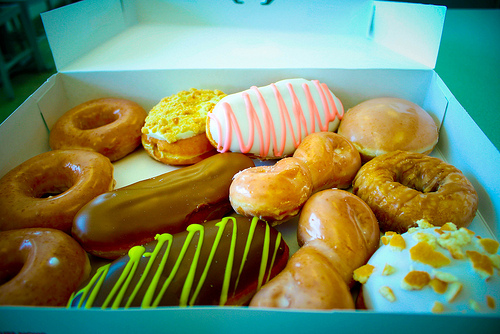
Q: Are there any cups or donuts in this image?
A: Yes, there is a donut.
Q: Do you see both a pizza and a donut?
A: No, there is a donut but no pizzas.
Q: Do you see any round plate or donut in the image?
A: Yes, there is a round donut.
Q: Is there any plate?
A: No, there are no plates.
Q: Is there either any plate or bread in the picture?
A: No, there are no plates or breads.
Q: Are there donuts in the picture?
A: Yes, there is a donut.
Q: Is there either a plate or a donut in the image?
A: Yes, there is a donut.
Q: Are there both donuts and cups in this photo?
A: No, there is a donut but no cups.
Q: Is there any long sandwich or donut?
A: Yes, there is a long donut.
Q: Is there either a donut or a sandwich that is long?
A: Yes, the donut is long.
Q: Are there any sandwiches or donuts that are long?
A: Yes, the donut is long.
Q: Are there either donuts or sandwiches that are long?
A: Yes, the donut is long.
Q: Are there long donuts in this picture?
A: Yes, there is a long donut.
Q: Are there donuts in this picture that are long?
A: Yes, there is a donut that is long.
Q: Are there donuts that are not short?
A: Yes, there is a long donut.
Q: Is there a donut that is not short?
A: Yes, there is a long donut.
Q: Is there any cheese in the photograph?
A: No, there is no cheese.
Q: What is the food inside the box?
A: The food is a donut.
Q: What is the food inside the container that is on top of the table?
A: The food is a donut.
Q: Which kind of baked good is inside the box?
A: The food is a donut.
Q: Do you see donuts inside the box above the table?
A: Yes, there is a donut inside the box.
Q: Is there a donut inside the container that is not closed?
A: Yes, there is a donut inside the box.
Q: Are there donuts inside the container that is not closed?
A: Yes, there is a donut inside the box.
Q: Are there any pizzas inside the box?
A: No, there is a donut inside the box.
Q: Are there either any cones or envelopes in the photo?
A: No, there are no envelopes or cones.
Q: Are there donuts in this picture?
A: Yes, there is a donut.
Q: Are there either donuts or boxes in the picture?
A: Yes, there is a donut.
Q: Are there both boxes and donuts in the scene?
A: Yes, there are both a donut and a box.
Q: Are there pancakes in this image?
A: No, there are no pancakes.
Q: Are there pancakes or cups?
A: No, there are no pancakes or cups.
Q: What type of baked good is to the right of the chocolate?
A: The food is a donut.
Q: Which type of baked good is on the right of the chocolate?
A: The food is a donut.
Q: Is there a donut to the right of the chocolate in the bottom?
A: Yes, there is a donut to the right of the chocolate.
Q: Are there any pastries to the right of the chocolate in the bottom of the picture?
A: No, there is a donut to the right of the chocolate.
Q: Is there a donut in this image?
A: Yes, there is a donut.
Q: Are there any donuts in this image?
A: Yes, there is a donut.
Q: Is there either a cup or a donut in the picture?
A: Yes, there is a donut.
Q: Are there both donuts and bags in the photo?
A: No, there is a donut but no bags.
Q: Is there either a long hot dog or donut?
A: Yes, there is a long donut.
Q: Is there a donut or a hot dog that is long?
A: Yes, the donut is long.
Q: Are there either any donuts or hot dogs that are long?
A: Yes, the donut is long.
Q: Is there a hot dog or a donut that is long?
A: Yes, the donut is long.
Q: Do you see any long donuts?
A: Yes, there is a long donut.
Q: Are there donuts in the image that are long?
A: Yes, there is a donut that is long.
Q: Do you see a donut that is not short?
A: Yes, there is a long donut.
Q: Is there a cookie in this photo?
A: No, there are no cookies.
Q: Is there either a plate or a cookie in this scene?
A: No, there are no cookies or plates.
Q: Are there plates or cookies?
A: No, there are no cookies or plates.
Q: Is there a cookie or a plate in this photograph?
A: No, there are no cookies or plates.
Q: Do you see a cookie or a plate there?
A: No, there are no cookies or plates.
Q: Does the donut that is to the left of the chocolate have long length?
A: Yes, the donut is long.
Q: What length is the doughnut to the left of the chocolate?
A: The doughnut is long.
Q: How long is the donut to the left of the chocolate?
A: The donut is long.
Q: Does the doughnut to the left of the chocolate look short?
A: No, the doughnut is long.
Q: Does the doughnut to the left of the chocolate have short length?
A: No, the doughnut is long.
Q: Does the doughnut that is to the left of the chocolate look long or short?
A: The doughnut is long.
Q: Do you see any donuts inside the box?
A: Yes, there is a donut inside the box.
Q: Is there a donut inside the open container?
A: Yes, there is a donut inside the box.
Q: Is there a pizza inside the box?
A: No, there is a donut inside the box.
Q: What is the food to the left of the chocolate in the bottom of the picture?
A: The food is a donut.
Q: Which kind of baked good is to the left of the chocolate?
A: The food is a donut.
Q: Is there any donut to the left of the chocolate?
A: Yes, there is a donut to the left of the chocolate.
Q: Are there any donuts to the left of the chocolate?
A: Yes, there is a donut to the left of the chocolate.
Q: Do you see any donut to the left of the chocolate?
A: Yes, there is a donut to the left of the chocolate.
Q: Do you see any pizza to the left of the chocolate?
A: No, there is a donut to the left of the chocolate.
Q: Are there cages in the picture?
A: No, there are no cages.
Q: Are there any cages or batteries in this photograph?
A: No, there are no cages or batteries.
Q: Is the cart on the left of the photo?
A: Yes, the cart is on the left of the image.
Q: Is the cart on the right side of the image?
A: No, the cart is on the left of the image.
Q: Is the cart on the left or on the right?
A: The cart is on the left of the image.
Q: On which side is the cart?
A: The cart is on the left of the image.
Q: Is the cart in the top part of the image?
A: Yes, the cart is in the top of the image.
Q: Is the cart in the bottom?
A: No, the cart is in the top of the image.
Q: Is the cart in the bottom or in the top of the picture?
A: The cart is in the top of the image.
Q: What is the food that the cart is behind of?
A: The food is donuts.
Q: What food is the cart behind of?
A: The cart is behind the doughnuts.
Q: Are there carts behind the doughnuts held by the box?
A: Yes, there is a cart behind the doughnuts.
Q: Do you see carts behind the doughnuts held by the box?
A: Yes, there is a cart behind the doughnuts.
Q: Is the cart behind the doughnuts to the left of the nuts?
A: Yes, the cart is behind the donuts.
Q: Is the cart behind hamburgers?
A: No, the cart is behind the donuts.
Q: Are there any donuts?
A: Yes, there is a donut.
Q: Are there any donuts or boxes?
A: Yes, there is a donut.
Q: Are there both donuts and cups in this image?
A: No, there is a donut but no cups.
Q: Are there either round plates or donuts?
A: Yes, there is a round donut.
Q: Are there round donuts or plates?
A: Yes, there is a round donut.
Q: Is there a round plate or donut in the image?
A: Yes, there is a round donut.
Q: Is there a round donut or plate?
A: Yes, there is a round donut.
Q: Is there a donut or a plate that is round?
A: Yes, the donut is round.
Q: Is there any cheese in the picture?
A: No, there is no cheese.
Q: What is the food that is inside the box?
A: The food is a donut.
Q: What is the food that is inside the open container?
A: The food is a donut.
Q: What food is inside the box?
A: The food is a donut.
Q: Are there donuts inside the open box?
A: Yes, there is a donut inside the box.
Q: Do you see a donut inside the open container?
A: Yes, there is a donut inside the box.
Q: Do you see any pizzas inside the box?
A: No, there is a donut inside the box.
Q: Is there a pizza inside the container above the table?
A: No, there is a donut inside the box.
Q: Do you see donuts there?
A: Yes, there is a donut.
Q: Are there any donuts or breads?
A: Yes, there is a donut.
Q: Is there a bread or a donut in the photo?
A: Yes, there is a donut.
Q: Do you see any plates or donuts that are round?
A: Yes, the donut is round.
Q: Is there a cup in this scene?
A: No, there are no cups.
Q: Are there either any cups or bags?
A: No, there are no cups or bags.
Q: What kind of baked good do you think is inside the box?
A: The food is a donut.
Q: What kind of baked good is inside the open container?
A: The food is a donut.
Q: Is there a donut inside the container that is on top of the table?
A: Yes, there is a donut inside the box.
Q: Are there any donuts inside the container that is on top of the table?
A: Yes, there is a donut inside the box.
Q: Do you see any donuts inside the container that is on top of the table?
A: Yes, there is a donut inside the box.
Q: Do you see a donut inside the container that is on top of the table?
A: Yes, there is a donut inside the box.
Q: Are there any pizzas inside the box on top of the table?
A: No, there is a donut inside the box.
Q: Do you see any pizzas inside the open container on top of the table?
A: No, there is a donut inside the box.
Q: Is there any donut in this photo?
A: Yes, there is a donut.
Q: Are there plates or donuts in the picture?
A: Yes, there is a donut.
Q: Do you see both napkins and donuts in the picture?
A: No, there is a donut but no napkins.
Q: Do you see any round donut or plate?
A: Yes, there is a round donut.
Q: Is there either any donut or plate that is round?
A: Yes, the donut is round.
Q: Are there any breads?
A: No, there are no breads.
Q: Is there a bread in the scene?
A: No, there is no breads.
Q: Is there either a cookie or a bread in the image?
A: No, there are no breads or cookies.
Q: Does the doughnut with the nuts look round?
A: Yes, the doughnut is round.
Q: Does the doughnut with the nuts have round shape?
A: Yes, the doughnut is round.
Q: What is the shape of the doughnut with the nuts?
A: The doughnut is round.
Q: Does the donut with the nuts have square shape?
A: No, the doughnut is round.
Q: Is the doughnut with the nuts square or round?
A: The donut is round.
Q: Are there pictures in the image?
A: No, there are no pictures.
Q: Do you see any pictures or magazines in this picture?
A: No, there are no pictures or magazines.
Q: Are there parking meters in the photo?
A: No, there are no parking meters.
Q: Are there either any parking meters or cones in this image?
A: No, there are no parking meters or cones.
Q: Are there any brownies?
A: No, there are no brownies.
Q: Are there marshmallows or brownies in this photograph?
A: No, there are no brownies or marshmallows.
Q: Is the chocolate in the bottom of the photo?
A: Yes, the chocolate is in the bottom of the image.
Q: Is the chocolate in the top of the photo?
A: No, the chocolate is in the bottom of the image.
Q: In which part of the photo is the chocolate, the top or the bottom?
A: The chocolate is in the bottom of the image.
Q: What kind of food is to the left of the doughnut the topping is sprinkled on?
A: The food is chocolate.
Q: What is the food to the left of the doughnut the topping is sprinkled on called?
A: The food is chocolate.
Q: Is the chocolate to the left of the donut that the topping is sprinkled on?
A: Yes, the chocolate is to the left of the doughnut.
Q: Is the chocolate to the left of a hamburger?
A: No, the chocolate is to the left of the doughnut.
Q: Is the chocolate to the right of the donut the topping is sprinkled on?
A: No, the chocolate is to the left of the donut.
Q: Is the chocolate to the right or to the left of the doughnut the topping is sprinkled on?
A: The chocolate is to the left of the doughnut.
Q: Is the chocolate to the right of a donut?
A: Yes, the chocolate is to the right of a donut.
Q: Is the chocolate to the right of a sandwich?
A: No, the chocolate is to the right of a donut.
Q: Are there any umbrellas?
A: No, there are no umbrellas.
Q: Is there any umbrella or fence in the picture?
A: No, there are no umbrellas or fences.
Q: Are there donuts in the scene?
A: Yes, there is a donut.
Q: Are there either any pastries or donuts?
A: Yes, there is a donut.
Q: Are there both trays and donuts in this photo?
A: No, there is a donut but no trays.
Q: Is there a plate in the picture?
A: No, there are no plates.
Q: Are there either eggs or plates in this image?
A: No, there are no plates or eggs.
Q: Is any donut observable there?
A: Yes, there is a donut.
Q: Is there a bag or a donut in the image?
A: Yes, there is a donut.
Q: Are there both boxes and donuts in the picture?
A: Yes, there are both a donut and a box.